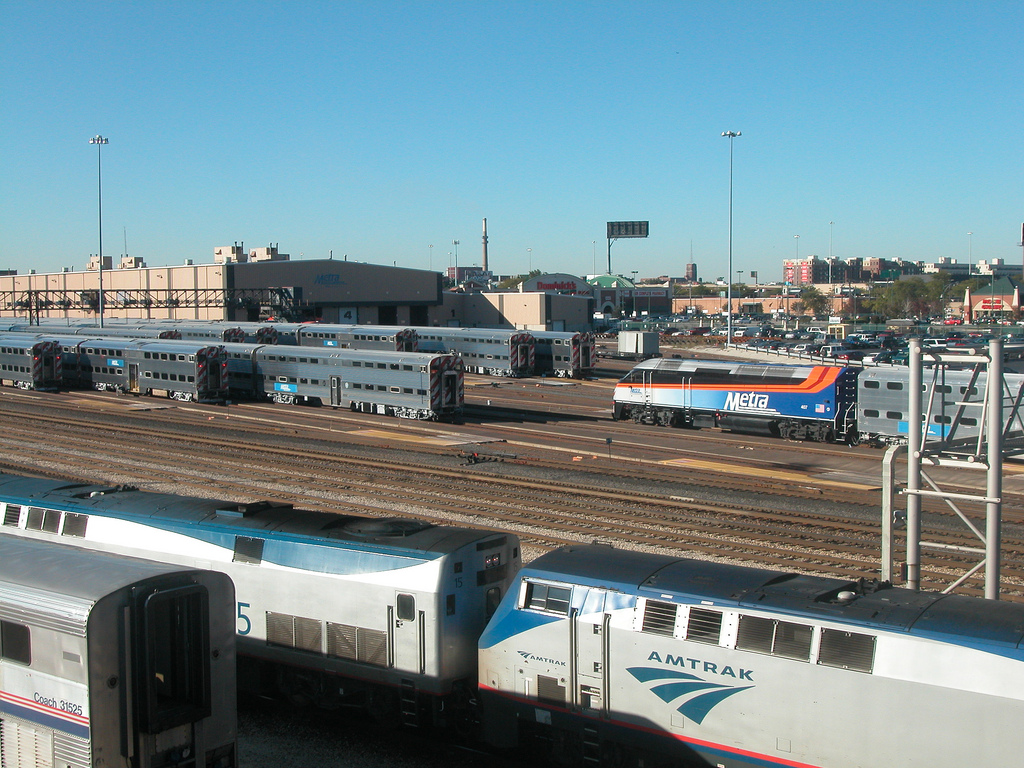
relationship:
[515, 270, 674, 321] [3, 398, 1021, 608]
building by tracks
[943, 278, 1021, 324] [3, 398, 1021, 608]
building by tracks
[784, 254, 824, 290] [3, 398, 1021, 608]
building by tracks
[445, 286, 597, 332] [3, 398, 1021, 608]
building by tracks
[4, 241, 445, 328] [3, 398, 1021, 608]
building by tracks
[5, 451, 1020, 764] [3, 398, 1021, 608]
train on tracks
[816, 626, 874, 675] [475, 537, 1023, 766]
window on train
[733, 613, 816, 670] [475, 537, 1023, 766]
window on train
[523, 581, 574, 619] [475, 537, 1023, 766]
window on train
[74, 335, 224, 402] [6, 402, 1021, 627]
train on tracks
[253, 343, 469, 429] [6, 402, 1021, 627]
train on tracks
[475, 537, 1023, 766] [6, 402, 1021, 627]
train on tracks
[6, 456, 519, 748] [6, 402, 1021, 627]
train on tracks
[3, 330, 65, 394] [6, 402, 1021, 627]
train on tracks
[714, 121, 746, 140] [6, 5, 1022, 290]
light in sky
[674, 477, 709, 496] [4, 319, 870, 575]
gravel on tracks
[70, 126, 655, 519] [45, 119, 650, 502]
windows on building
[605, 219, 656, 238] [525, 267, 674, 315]
sign over building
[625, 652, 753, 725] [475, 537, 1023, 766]
logo on side of train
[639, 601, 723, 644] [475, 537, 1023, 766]
vents on side of train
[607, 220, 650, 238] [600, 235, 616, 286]
sign on pole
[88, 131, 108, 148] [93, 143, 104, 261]
lights on pole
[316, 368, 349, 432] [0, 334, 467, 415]
door on train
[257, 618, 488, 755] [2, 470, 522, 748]
window on train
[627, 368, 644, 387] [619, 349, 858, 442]
window on engine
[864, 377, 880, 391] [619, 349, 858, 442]
window on engine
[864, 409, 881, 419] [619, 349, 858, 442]
window on engine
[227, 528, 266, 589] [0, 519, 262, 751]
glass window on train engine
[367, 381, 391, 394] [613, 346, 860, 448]
window on train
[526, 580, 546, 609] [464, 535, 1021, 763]
glass window on train engine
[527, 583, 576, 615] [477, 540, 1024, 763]
window on train engine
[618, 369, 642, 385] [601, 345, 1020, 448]
window on train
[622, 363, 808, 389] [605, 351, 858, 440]
window on train